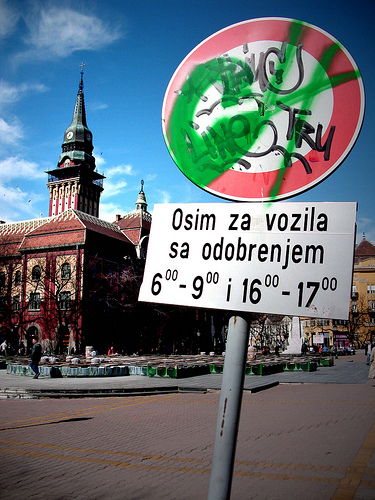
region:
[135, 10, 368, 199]
Red and white sign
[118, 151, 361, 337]
White and black sign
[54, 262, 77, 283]
Small window on a building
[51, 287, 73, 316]
Small window on a building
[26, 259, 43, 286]
Small window on a building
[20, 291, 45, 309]
Small window on a building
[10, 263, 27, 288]
Small window on a building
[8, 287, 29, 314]
Small window on a building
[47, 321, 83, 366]
Small window on a building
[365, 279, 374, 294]
Small window on a building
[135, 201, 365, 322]
a black and white sign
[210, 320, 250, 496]
a gray metal post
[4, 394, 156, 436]
a yellow line in the road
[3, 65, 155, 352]
a red and cream building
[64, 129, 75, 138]
a clock on a tower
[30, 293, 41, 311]
a window on a building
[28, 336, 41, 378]
people on a side walk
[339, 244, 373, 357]
tan building in the distance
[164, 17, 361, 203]
a red and white sign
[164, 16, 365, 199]
a red and white sign with green paint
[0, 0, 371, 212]
blue of daytime sky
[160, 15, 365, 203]
red on circular sign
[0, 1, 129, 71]
thin white cloud in sky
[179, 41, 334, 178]
graffiti in black paint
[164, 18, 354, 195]
green paint on circular sign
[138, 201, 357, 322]
black letters on white sign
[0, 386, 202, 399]
puddle of water under curb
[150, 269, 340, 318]
numbers on bottom of sign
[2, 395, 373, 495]
yellow lines on street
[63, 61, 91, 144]
cross on church dome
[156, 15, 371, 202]
graffiti over graffiti on street sign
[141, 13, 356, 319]
Double street sign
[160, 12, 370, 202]
red street sign with graffiti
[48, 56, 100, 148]
Church steeple with clock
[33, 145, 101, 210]
Red church bell tower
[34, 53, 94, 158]
Green church steeple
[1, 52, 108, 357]
Red church with green steeple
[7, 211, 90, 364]
Windows on a church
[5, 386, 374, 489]
Yellow striped brick roadway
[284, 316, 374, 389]
Storefronts in village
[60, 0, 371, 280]
spray paint on sign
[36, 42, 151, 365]
a clock tower in europe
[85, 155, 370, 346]
the sign has times on it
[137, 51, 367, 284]
the spray paint is green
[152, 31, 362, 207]
the text is black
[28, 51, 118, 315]
the roof is green spire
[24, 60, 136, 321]
red brick building on corner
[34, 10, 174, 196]
the sky has clouds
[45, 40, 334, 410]
scene in a european plaza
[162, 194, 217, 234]
this word is osim